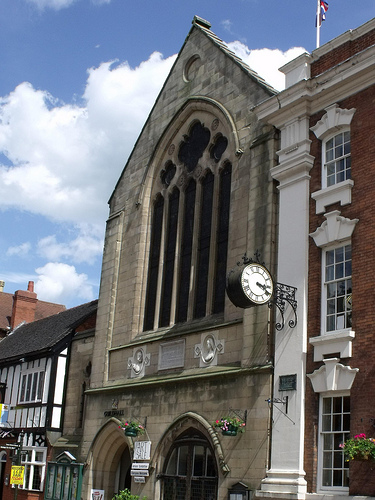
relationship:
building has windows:
[6, 293, 75, 498] [18, 372, 46, 406]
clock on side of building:
[225, 262, 273, 310] [96, 6, 369, 309]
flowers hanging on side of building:
[114, 412, 141, 438] [76, 13, 272, 497]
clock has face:
[225, 262, 273, 310] [241, 262, 273, 303]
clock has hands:
[225, 262, 273, 310] [255, 281, 271, 296]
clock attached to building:
[225, 262, 273, 310] [238, 49, 368, 495]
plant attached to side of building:
[214, 415, 247, 435] [103, 69, 276, 495]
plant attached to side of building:
[117, 413, 144, 437] [103, 69, 276, 495]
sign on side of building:
[259, 370, 312, 393] [94, 37, 299, 491]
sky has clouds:
[0, 1, 372, 314] [11, 126, 105, 296]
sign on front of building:
[132, 438, 149, 459] [81, 13, 374, 498]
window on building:
[126, 90, 247, 347] [38, 16, 280, 498]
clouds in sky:
[2, 42, 315, 314] [0, 1, 372, 314]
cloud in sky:
[22, 260, 95, 307] [0, 1, 372, 314]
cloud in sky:
[0, 38, 305, 237] [0, 1, 372, 314]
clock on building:
[225, 262, 273, 310] [251, 16, 370, 498]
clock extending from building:
[225, 262, 273, 310] [85, 7, 370, 349]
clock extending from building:
[225, 262, 273, 310] [251, 16, 370, 498]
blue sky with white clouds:
[2, 0, 373, 106] [1, 40, 310, 310]